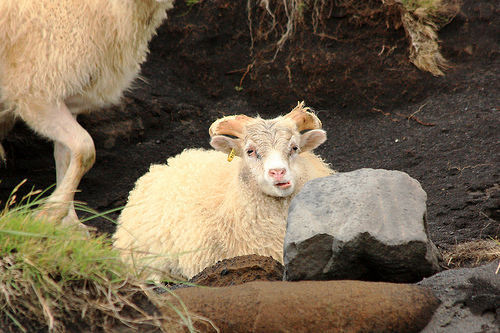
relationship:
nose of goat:
[269, 168, 285, 177] [103, 93, 387, 283]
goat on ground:
[111, 102, 338, 283] [0, 98, 483, 329]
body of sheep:
[128, 149, 268, 260] [123, 94, 363, 295]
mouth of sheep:
[272, 179, 292, 189] [98, 93, 342, 281]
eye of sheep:
[245, 146, 254, 157] [120, 120, 358, 271]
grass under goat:
[0, 178, 220, 331] [1, 0, 169, 254]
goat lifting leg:
[111, 102, 338, 283] [27, 93, 109, 221]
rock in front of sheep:
[281, 167, 441, 281] [121, 109, 342, 282]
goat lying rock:
[111, 102, 335, 283] [277, 142, 446, 279]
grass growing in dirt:
[0, 178, 220, 331] [0, 0, 499, 332]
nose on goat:
[269, 167, 284, 177] [111, 102, 338, 283]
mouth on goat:
[271, 176, 294, 193] [111, 102, 335, 283]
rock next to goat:
[281, 167, 441, 281] [111, 102, 335, 283]